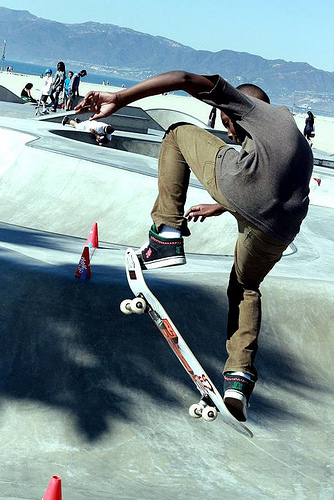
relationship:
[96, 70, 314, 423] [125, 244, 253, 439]
boy on board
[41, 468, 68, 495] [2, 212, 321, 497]
cone on ramp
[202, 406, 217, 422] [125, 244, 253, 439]
wheel on board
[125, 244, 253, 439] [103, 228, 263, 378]
board in air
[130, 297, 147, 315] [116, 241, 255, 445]
wheel on skateboard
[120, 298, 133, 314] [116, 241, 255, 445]
wheel on skateboard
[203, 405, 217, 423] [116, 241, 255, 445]
wheel on skateboard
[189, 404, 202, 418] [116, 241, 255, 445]
wheel on skateboard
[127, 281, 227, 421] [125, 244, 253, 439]
back of board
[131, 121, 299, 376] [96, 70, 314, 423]
jeans on boy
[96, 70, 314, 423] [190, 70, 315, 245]
boy wearing shirt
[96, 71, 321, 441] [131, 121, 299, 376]
boy wearing jeans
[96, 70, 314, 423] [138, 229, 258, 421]
boy wearing shoes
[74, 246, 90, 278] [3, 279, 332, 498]
cone on ramp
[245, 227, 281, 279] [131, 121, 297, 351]
pockets on jeans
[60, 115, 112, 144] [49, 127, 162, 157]
person looking at hole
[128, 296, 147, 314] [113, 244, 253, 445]
wheel on board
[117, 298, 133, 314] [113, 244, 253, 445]
wheel on board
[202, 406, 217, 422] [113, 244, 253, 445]
wheel on board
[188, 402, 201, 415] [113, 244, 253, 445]
wheel on board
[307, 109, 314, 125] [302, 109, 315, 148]
hair on girl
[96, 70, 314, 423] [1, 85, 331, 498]
boy sitting on concrete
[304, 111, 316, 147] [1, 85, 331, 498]
girl sitting on concrete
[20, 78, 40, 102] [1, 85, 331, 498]
person sitting on concrete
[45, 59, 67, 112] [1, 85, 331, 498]
person sitting on concrete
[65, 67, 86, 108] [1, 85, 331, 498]
person sitting on concrete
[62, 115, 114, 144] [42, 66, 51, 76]
person wearing helmet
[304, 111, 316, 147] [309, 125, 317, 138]
girl carrying purse